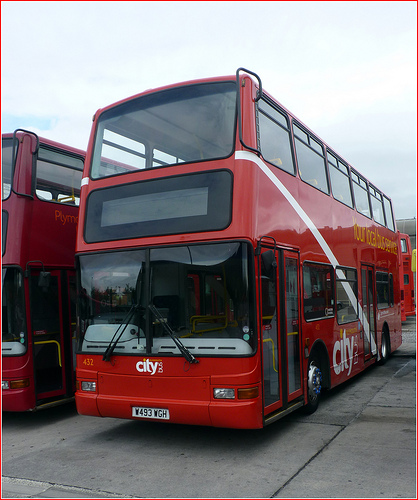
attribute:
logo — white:
[111, 346, 179, 382]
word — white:
[134, 358, 159, 376]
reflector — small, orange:
[235, 385, 259, 401]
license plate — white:
[130, 402, 170, 421]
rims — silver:
[307, 359, 324, 400]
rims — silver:
[381, 336, 386, 355]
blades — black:
[100, 304, 138, 363]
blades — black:
[146, 304, 197, 366]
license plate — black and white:
[130, 404, 170, 420]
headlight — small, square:
[213, 388, 235, 399]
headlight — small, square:
[81, 380, 98, 390]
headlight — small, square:
[4, 379, 9, 389]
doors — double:
[214, 232, 369, 426]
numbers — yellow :
[78, 355, 95, 366]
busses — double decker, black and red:
[72, 66, 403, 430]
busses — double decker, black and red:
[1, 127, 141, 414]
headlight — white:
[214, 387, 236, 399]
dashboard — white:
[76, 317, 252, 354]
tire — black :
[284, 354, 340, 439]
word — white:
[332, 329, 354, 376]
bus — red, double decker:
[68, 67, 402, 435]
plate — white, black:
[132, 404, 169, 418]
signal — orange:
[235, 378, 259, 403]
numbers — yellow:
[77, 352, 96, 370]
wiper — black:
[139, 296, 197, 367]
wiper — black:
[98, 298, 139, 361]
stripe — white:
[234, 147, 378, 356]